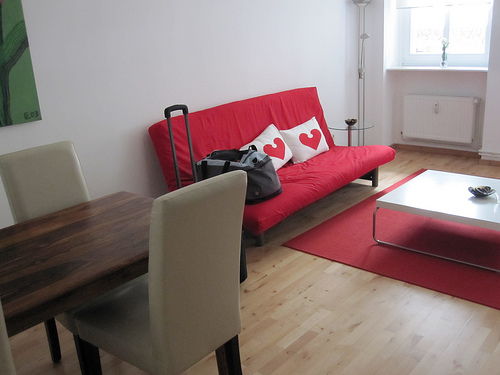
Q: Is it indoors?
A: Yes, it is indoors.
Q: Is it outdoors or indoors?
A: It is indoors.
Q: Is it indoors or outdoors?
A: It is indoors.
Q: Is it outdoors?
A: No, it is indoors.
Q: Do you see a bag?
A: Yes, there is a bag.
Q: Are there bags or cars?
A: Yes, there is a bag.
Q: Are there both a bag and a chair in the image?
A: Yes, there are both a bag and a chair.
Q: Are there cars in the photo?
A: No, there are no cars.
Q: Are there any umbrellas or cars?
A: No, there are no cars or umbrellas.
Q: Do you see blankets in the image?
A: No, there are no blankets.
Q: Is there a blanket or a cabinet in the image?
A: No, there are no blankets or cabinets.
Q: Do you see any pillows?
A: Yes, there is a pillow.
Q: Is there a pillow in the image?
A: Yes, there is a pillow.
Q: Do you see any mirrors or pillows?
A: Yes, there is a pillow.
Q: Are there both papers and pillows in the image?
A: No, there is a pillow but no papers.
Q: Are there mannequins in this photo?
A: No, there are no mannequins.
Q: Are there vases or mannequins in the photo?
A: No, there are no mannequins or vases.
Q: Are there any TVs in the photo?
A: No, there are no tvs.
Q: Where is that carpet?
A: The carpet is on the floor.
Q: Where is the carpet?
A: The carpet is on the floor.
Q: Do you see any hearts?
A: Yes, there is a heart.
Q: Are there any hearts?
A: Yes, there is a heart.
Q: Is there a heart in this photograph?
A: Yes, there is a heart.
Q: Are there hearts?
A: Yes, there is a heart.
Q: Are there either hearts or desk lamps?
A: Yes, there is a heart.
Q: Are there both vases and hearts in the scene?
A: No, there is a heart but no vases.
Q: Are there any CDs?
A: No, there are no cds.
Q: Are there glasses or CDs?
A: No, there are no CDs or glasses.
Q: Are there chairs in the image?
A: Yes, there is a chair.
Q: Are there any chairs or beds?
A: Yes, there is a chair.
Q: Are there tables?
A: Yes, there is a table.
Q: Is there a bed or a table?
A: Yes, there is a table.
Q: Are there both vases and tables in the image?
A: No, there is a table but no vases.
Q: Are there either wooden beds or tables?
A: Yes, there is a wood table.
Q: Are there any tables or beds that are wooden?
A: Yes, the table is wooden.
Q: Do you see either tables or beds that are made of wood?
A: Yes, the table is made of wood.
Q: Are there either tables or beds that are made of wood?
A: Yes, the table is made of wood.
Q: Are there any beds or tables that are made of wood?
A: Yes, the table is made of wood.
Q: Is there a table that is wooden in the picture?
A: Yes, there is a wood table.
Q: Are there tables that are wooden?
A: Yes, there is a table that is wooden.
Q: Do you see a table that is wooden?
A: Yes, there is a table that is wooden.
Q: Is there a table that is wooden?
A: Yes, there is a table that is wooden.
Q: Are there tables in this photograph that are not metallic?
A: Yes, there is a wooden table.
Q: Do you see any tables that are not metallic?
A: Yes, there is a wooden table.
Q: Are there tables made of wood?
A: Yes, there is a table that is made of wood.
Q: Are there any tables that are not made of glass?
A: Yes, there is a table that is made of wood.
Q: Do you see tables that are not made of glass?
A: Yes, there is a table that is made of wood.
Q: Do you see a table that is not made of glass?
A: Yes, there is a table that is made of wood.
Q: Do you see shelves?
A: No, there are no shelves.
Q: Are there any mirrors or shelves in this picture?
A: No, there are no shelves or mirrors.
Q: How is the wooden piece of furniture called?
A: The piece of furniture is a table.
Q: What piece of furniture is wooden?
A: The piece of furniture is a table.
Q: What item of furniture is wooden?
A: The piece of furniture is a table.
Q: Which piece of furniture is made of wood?
A: The piece of furniture is a table.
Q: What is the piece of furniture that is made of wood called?
A: The piece of furniture is a table.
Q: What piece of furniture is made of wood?
A: The piece of furniture is a table.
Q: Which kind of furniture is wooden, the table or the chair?
A: The table is wooden.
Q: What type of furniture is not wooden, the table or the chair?
A: The chair is not wooden.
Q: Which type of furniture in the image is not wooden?
A: The furniture is a chair.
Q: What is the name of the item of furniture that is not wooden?
A: The piece of furniture is a chair.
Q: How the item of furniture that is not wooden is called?
A: The piece of furniture is a chair.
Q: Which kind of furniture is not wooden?
A: The furniture is a chair.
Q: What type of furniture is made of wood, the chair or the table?
A: The table is made of wood.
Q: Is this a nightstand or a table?
A: This is a table.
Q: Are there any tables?
A: Yes, there is a table.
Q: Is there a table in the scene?
A: Yes, there is a table.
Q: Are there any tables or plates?
A: Yes, there is a table.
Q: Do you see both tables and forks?
A: No, there is a table but no forks.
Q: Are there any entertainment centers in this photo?
A: No, there are no entertainment centers.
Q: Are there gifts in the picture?
A: No, there are no gifts.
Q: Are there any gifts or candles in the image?
A: No, there are no gifts or candles.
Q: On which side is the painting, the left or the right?
A: The painting is on the left of the image.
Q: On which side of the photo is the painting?
A: The painting is on the left of the image.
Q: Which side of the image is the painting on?
A: The painting is on the left of the image.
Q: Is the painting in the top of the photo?
A: Yes, the painting is in the top of the image.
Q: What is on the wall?
A: The painting is on the wall.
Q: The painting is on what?
A: The painting is on the wall.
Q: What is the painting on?
A: The painting is on the wall.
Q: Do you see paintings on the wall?
A: Yes, there is a painting on the wall.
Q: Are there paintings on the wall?
A: Yes, there is a painting on the wall.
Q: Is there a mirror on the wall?
A: No, there is a painting on the wall.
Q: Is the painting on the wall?
A: Yes, the painting is on the wall.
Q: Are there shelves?
A: No, there are no shelves.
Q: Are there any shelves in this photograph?
A: No, there are no shelves.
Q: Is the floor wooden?
A: Yes, the floor is wooden.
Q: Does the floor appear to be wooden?
A: Yes, the floor is wooden.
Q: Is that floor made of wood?
A: Yes, the floor is made of wood.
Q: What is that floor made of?
A: The floor is made of wood.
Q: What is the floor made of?
A: The floor is made of wood.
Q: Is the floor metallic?
A: No, the floor is wooden.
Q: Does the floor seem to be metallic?
A: No, the floor is wooden.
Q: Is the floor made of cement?
A: No, the floor is made of wood.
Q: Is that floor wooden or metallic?
A: The floor is wooden.